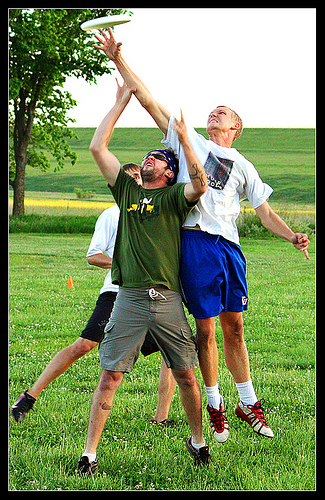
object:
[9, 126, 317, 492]
field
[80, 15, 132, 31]
frisbee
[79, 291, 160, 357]
shorts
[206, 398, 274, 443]
shoes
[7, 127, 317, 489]
grass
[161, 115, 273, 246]
tee shirt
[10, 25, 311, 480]
men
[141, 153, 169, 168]
sunglasses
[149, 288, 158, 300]
knot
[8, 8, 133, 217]
tree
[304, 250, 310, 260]
finger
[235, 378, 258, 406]
sock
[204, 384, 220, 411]
sock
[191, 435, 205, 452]
sock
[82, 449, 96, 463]
sock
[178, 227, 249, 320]
shorts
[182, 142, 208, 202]
forearm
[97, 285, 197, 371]
shorts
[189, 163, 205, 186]
tattoo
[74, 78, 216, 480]
man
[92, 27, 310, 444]
man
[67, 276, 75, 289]
cone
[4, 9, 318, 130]
air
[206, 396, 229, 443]
cleat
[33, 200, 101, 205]
flower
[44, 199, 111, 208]
flower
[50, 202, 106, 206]
flower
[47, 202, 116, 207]
flower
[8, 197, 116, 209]
flower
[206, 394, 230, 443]
athletic shoe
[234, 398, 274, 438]
athletic shoe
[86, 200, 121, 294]
shirt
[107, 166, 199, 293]
shirt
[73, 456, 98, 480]
shoe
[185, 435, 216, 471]
shoe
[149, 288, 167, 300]
drawstring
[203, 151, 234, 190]
design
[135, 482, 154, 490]
flowers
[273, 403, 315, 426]
flowers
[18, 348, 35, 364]
flowers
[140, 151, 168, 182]
face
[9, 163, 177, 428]
man